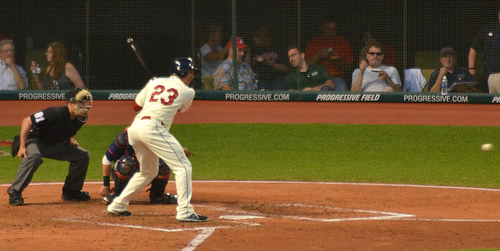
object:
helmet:
[168, 51, 200, 82]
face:
[434, 47, 464, 74]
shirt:
[133, 73, 197, 120]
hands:
[67, 135, 79, 145]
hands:
[14, 144, 28, 156]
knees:
[76, 148, 91, 160]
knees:
[27, 152, 41, 164]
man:
[274, 40, 332, 99]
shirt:
[281, 66, 326, 96]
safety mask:
[64, 86, 94, 115]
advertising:
[224, 94, 292, 103]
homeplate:
[216, 208, 263, 225]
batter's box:
[228, 189, 406, 236]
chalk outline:
[52, 207, 259, 233]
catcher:
[106, 120, 209, 213]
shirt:
[303, 38, 358, 75]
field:
[0, 0, 497, 243]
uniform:
[5, 68, 110, 210]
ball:
[478, 139, 493, 157]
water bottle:
[436, 72, 451, 99]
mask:
[73, 90, 93, 122]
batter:
[107, 56, 209, 221]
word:
[313, 92, 381, 102]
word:
[402, 92, 474, 103]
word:
[225, 92, 291, 100]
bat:
[127, 35, 152, 76]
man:
[103, 55, 209, 222]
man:
[352, 40, 402, 91]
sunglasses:
[368, 50, 383, 56]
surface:
[219, 215, 274, 217]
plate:
[219, 210, 264, 223]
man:
[0, 35, 32, 102]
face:
[0, 43, 19, 63]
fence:
[4, 8, 497, 88]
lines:
[232, 191, 426, 249]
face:
[68, 92, 95, 119]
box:
[54, 203, 242, 234]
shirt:
[20, 105, 105, 145]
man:
[9, 83, 96, 203]